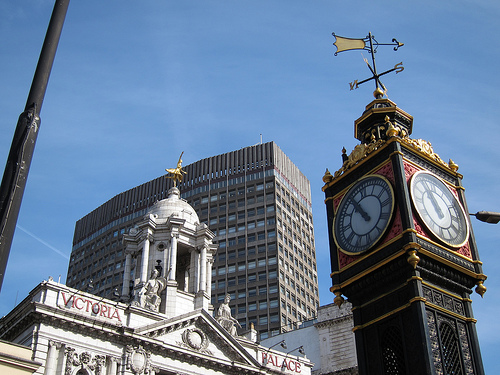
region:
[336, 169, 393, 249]
black and white clock in clock tower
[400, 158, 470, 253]
black and white clock in clock tower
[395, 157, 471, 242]
black and white clock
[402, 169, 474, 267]
clock in clock tower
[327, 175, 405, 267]
clock in clock tower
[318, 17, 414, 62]
weather vane on clock tower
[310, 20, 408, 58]
yellow weather vane on clock tower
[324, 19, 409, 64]
yellow weather vane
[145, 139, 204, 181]
gold top of building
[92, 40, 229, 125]
white clouds against blue sky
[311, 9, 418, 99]
Spinning metal piece that indicates the direction of the wind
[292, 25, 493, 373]
Tall clock tower with a large black tower and wider red portion with a clock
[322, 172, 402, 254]
White clock face with black hands and black roman numerals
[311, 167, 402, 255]
Clock with a red background on a clock tower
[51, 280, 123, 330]
White building with red letters reading Victoria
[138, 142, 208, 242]
Golden statue topping the dome of a white building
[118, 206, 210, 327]
White marble building with columns and greek inspired architecture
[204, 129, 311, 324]
Tall grayish modern building in the distance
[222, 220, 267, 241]
Row of clear windows reflecting a blue skyline in a building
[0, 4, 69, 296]
Tall black metal pole with a blue sky behind it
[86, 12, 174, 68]
white clouds in blue sky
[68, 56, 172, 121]
white clouds in blue sky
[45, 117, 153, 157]
white clouds in blue sky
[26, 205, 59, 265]
white clouds in blue sky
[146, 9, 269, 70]
white clouds in blue sky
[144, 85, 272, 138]
white clouds in blue sky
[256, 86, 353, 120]
white clouds in blue sky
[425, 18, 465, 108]
white clouds in blue sky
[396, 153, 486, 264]
black and white clock in tower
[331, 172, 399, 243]
black and white clock in tower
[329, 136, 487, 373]
a clock on a black metal tower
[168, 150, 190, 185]
golden scultpure atop a buildin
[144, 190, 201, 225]
a stone dome on a building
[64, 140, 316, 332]
a large high rise building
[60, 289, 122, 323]
red lettering on a white building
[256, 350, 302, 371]
red lettering on a white building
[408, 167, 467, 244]
a clock face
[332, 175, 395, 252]
a white and black clock face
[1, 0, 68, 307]
a black metal pole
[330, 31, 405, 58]
a metal arrow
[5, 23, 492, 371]
a clock on a tower and buildings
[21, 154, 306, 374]
a Victoria Palace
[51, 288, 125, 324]
a word VICTORIA on the bluiding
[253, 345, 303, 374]
a word PALACE on the building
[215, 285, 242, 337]
a statue on the Victoria Palace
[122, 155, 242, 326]
an architectural structure on top of the Victoria Palace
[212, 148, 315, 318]
a building close the Victoria Place building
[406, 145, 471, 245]
a clock on top of the tower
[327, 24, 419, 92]
a weather vane on top of the tower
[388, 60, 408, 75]
an S sign of the weather vane